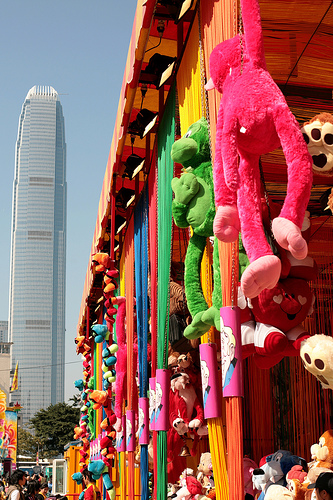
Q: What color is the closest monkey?
A: Pink.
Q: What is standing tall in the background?
A: A skyscraper.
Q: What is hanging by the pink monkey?
A: A giant paw.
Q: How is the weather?
A: Clear.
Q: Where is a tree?
A: At the end of the animal displays.